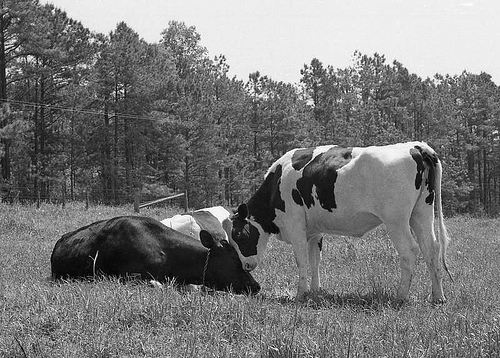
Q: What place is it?
A: It is a pasture.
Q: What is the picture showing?
A: It is showing a pasture.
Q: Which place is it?
A: It is a pasture.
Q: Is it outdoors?
A: Yes, it is outdoors.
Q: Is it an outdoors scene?
A: Yes, it is outdoors.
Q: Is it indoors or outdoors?
A: It is outdoors.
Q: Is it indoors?
A: No, it is outdoors.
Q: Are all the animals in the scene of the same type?
A: Yes, all the animals are cows.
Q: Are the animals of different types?
A: No, all the animals are cows.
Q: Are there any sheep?
A: No, there are no sheep.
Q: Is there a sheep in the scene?
A: No, there is no sheep.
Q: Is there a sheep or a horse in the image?
A: No, there are no sheep or horses.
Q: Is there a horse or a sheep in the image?
A: No, there are no sheep or horses.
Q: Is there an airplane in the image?
A: No, there are no airplanes.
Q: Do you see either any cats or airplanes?
A: No, there are no airplanes or cats.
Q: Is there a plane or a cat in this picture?
A: No, there are no airplanes or cats.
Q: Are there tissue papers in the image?
A: No, there are no tissue papers.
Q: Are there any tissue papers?
A: No, there are no tissue papers.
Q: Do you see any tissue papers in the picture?
A: No, there are no tissue papers.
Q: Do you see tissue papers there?
A: No, there are no tissue papers.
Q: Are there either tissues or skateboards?
A: No, there are no tissues or skateboards.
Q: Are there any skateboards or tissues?
A: No, there are no tissues or skateboards.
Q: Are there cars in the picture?
A: No, there are no cars.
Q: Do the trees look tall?
A: Yes, the trees are tall.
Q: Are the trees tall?
A: Yes, the trees are tall.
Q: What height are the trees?
A: The trees are tall.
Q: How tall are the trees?
A: The trees are tall.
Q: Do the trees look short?
A: No, the trees are tall.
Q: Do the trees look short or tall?
A: The trees are tall.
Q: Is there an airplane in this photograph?
A: No, there are no airplanes.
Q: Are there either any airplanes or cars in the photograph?
A: No, there are no airplanes or cars.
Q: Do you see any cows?
A: Yes, there is a cow.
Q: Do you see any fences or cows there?
A: Yes, there is a cow.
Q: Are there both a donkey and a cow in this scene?
A: No, there is a cow but no donkeys.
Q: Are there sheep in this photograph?
A: No, there are no sheep.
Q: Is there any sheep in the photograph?
A: No, there is no sheep.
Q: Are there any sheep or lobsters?
A: No, there are no sheep or lobsters.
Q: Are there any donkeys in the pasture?
A: No, there is a cow in the pasture.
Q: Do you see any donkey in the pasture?
A: No, there is a cow in the pasture.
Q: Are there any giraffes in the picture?
A: No, there are no giraffes.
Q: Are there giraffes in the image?
A: No, there are no giraffes.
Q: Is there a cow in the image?
A: Yes, there is a cow.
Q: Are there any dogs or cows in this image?
A: Yes, there is a cow.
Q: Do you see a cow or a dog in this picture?
A: Yes, there is a cow.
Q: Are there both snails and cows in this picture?
A: No, there is a cow but no snails.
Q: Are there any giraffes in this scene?
A: No, there are no giraffes.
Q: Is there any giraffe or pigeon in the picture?
A: No, there are no giraffes or pigeons.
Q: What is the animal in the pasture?
A: The animal is a cow.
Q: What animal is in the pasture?
A: The animal is a cow.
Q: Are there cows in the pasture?
A: Yes, there is a cow in the pasture.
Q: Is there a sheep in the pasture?
A: No, there is a cow in the pasture.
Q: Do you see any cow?
A: Yes, there is a cow.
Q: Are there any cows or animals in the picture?
A: Yes, there is a cow.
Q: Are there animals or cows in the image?
A: Yes, there is a cow.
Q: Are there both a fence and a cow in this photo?
A: Yes, there are both a cow and a fence.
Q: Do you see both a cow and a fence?
A: Yes, there are both a cow and a fence.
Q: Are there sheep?
A: No, there are no sheep.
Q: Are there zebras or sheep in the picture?
A: No, there are no sheep or zebras.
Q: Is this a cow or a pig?
A: This is a cow.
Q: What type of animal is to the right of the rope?
A: The animal is a cow.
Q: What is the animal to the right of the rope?
A: The animal is a cow.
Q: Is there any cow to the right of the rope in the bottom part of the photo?
A: Yes, there is a cow to the right of the rope.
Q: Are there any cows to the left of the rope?
A: No, the cow is to the right of the rope.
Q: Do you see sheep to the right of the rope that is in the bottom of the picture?
A: No, there is a cow to the right of the rope.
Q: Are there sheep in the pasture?
A: No, there is a cow in the pasture.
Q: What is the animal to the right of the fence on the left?
A: The animal is a cow.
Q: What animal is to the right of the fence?
A: The animal is a cow.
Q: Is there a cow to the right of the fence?
A: Yes, there is a cow to the right of the fence.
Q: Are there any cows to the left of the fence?
A: No, the cow is to the right of the fence.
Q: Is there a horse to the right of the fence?
A: No, there is a cow to the right of the fence.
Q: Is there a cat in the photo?
A: No, there are no cats.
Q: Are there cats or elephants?
A: No, there are no cats or elephants.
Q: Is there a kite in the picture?
A: No, there are no kites.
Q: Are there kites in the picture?
A: No, there are no kites.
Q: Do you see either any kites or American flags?
A: No, there are no kites or American flags.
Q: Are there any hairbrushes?
A: No, there are no hairbrushes.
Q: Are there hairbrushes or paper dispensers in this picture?
A: No, there are no hairbrushes or paper dispensers.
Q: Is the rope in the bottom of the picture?
A: Yes, the rope is in the bottom of the image.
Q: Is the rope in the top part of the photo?
A: No, the rope is in the bottom of the image.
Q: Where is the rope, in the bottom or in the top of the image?
A: The rope is in the bottom of the image.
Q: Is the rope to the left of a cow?
A: Yes, the rope is to the left of a cow.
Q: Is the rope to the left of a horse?
A: No, the rope is to the left of a cow.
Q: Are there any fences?
A: Yes, there is a fence.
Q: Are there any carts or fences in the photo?
A: Yes, there is a fence.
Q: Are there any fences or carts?
A: Yes, there is a fence.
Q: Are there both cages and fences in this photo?
A: No, there is a fence but no cages.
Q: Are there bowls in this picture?
A: No, there are no bowls.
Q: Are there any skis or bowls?
A: No, there are no bowls or skis.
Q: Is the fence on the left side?
A: Yes, the fence is on the left of the image.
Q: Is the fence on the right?
A: No, the fence is on the left of the image.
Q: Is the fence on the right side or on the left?
A: The fence is on the left of the image.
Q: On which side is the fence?
A: The fence is on the left of the image.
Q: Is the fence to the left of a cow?
A: Yes, the fence is to the left of a cow.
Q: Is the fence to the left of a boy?
A: No, the fence is to the left of a cow.